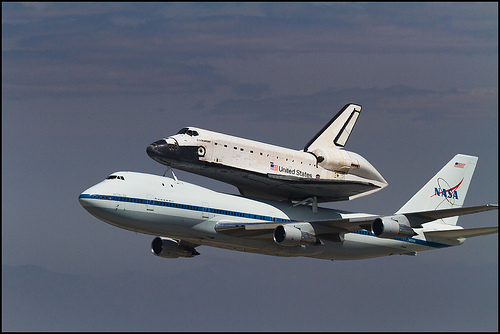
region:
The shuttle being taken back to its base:
[55, 87, 499, 327]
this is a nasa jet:
[86, 173, 470, 221]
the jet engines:
[143, 211, 415, 263]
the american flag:
[450, 157, 467, 174]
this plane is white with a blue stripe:
[73, 165, 494, 257]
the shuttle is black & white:
[123, 96, 392, 201]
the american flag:
[267, 155, 286, 174]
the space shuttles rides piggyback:
[82, 95, 496, 280]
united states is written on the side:
[269, 157, 319, 188]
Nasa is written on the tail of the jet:
[433, 170, 475, 215]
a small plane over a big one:
[57, 81, 494, 294]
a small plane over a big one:
[51, 81, 436, 298]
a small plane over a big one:
[66, 74, 480, 270]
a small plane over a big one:
[57, 98, 497, 306]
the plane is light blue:
[77, 169, 478, 284]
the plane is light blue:
[77, 171, 469, 328]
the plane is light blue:
[77, 173, 489, 273]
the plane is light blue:
[87, 161, 477, 282]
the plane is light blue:
[87, 171, 446, 283]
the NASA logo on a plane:
[390, 144, 477, 220]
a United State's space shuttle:
[118, 101, 420, 210]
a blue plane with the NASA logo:
[75, 151, 499, 269]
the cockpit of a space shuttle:
[142, 124, 217, 176]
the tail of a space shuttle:
[296, 94, 398, 177]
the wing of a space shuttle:
[268, 168, 385, 202]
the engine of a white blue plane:
[264, 220, 330, 252]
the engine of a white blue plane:
[370, 209, 418, 241]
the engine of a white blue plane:
[143, 230, 203, 267]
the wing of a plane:
[205, 201, 499, 238]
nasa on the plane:
[425, 170, 465, 204]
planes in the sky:
[80, 103, 492, 268]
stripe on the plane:
[63, 186, 280, 221]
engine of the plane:
[164, 238, 199, 255]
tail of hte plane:
[320, 101, 347, 151]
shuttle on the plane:
[161, 114, 376, 214]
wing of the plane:
[162, 205, 485, 223]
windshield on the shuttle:
[173, 123, 205, 140]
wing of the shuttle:
[227, 168, 367, 195]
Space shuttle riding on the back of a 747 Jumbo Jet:
[77, 102, 498, 259]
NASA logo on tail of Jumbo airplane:
[432, 175, 463, 215]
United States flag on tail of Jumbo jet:
[453, 160, 465, 168]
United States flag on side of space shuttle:
[267, 162, 275, 172]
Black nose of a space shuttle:
[145, 134, 167, 165]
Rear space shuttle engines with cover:
[344, 147, 389, 202]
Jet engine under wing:
[372, 217, 418, 239]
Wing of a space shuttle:
[269, 176, 379, 203]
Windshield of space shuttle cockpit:
[177, 128, 199, 137]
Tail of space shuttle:
[305, 103, 362, 148]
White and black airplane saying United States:
[142, 98, 391, 208]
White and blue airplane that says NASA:
[62, 149, 499, 281]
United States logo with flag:
[265, 155, 325, 179]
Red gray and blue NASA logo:
[428, 170, 467, 210]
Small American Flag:
[449, 158, 468, 170]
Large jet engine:
[144, 232, 204, 269]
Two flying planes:
[75, 96, 498, 270]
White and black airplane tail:
[304, 95, 368, 151]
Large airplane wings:
[211, 200, 498, 237]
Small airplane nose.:
[140, 131, 180, 171]